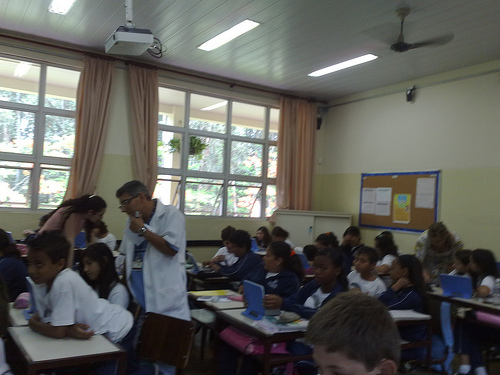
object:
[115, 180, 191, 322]
man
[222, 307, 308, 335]
desktop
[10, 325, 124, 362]
desktop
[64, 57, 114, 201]
drape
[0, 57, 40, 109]
window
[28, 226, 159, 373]
boy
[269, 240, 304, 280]
hair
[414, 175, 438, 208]
papers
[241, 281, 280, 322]
computer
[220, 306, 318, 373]
table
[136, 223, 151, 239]
wrist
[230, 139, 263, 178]
window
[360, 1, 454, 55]
fan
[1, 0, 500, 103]
ceiling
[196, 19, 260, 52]
light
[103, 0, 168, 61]
projector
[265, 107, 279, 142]
window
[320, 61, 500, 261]
wall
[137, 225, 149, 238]
wristwatch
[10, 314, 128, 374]
desk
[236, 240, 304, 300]
student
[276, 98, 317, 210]
drapes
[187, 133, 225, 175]
window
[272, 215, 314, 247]
cabinet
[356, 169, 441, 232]
board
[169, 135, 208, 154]
plant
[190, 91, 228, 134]
window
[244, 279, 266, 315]
screen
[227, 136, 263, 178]
pane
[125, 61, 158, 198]
curtain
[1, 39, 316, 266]
wall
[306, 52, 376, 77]
light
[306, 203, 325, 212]
corner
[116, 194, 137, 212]
glasses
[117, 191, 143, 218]
face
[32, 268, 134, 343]
shirt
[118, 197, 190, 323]
jacket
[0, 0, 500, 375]
class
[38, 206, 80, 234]
shirt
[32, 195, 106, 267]
woman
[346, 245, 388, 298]
boys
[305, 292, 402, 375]
child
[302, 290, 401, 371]
hair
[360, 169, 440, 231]
bullitin board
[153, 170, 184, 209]
windows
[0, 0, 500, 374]
classroom